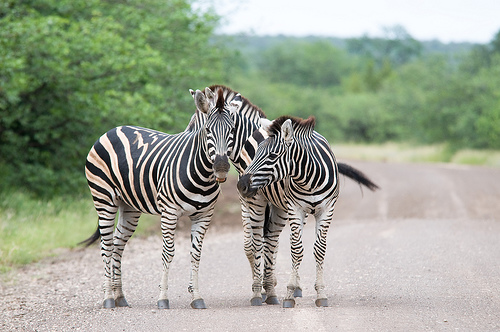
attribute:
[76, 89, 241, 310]
zebra — striped, standing, black, white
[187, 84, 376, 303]
zebra — striped, standing, black, white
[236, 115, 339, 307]
zebra — striped, standing, black, white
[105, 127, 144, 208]
stripes — black, white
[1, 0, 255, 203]
trees — green, bushy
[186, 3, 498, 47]
sky — white, gray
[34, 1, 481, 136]
background — blurry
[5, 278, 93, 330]
gravel — gray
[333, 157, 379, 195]
tail — black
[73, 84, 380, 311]
zebras — standing, black, white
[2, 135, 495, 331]
road — gravel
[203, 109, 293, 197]
faces — close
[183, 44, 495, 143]
vegetation — green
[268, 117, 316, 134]
mane — black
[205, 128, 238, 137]
eyes — open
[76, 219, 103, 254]
tail — black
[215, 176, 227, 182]
tongue — pink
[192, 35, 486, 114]
area — wooded